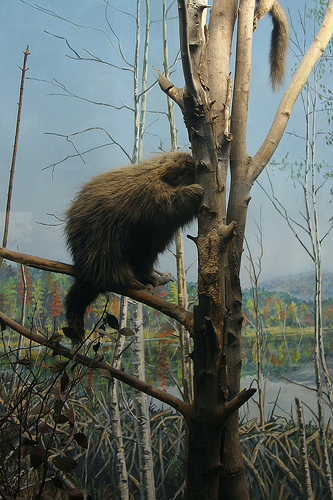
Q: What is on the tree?
A: Furry beaver on tree branch.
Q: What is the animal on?
A: Tree.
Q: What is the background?
A: Painting.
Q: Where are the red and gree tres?
A: Background.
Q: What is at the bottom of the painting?
A: Beaver damn.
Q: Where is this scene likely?
A: Museum.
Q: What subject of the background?
A: Pond.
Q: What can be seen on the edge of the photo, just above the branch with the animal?
A: Reflection.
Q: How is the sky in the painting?
A: Overcast.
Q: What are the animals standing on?
A: Tree branches.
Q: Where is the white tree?
A: Behind the animals.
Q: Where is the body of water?
A: Behind the trees in the distance.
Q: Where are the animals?
A: In a tree.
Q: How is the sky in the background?
A: Blue.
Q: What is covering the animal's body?
A: Brown fur.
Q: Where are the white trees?
A: Behind the brown trees.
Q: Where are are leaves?
A: On trees along water'e edge.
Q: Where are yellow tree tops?
A: In the distance at the water's edge.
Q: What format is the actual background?
A: A painting.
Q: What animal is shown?
A: A beaver.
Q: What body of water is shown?
A: A lake.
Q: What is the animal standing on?
A: A branch.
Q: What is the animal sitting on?
A: A branch.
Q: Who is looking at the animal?
A: The photographer.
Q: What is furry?
A: The animal in the tree.